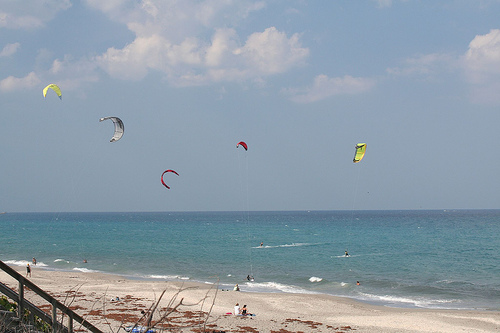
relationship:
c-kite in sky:
[159, 168, 180, 190] [1, 0, 480, 213]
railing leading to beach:
[6, 253, 109, 331] [4, 262, 498, 331]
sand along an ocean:
[4, 264, 498, 331] [4, 213, 498, 309]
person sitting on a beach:
[233, 302, 243, 316] [4, 262, 498, 331]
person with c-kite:
[224, 259, 264, 303] [235, 140, 249, 152]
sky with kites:
[0, 0, 500, 213] [177, 109, 283, 167]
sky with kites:
[0, 0, 500, 213] [48, 100, 385, 218]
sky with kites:
[35, 43, 495, 207] [97, 110, 426, 221]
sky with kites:
[0, 0, 500, 213] [45, 106, 226, 196]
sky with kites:
[0, 0, 500, 213] [115, 109, 387, 183]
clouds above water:
[122, 20, 333, 81] [88, 199, 496, 328]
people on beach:
[232, 300, 253, 318] [4, 233, 484, 331]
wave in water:
[300, 264, 337, 293] [0, 211, 484, 302]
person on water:
[244, 266, 262, 285] [5, 214, 480, 314]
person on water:
[344, 250, 350, 257] [5, 214, 480, 314]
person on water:
[354, 276, 371, 292] [5, 214, 480, 314]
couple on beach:
[230, 294, 254, 320] [4, 219, 466, 331]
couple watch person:
[230, 294, 254, 320] [356, 281, 359, 285]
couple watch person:
[230, 294, 254, 320] [246, 274, 251, 281]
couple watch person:
[230, 294, 254, 320] [344, 250, 350, 257]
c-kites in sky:
[35, 82, 370, 198] [1, 0, 480, 213]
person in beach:
[26, 263, 33, 277] [4, 219, 466, 331]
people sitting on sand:
[239, 304, 256, 316] [4, 264, 498, 331]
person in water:
[341, 240, 351, 263] [0, 211, 484, 302]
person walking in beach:
[22, 262, 34, 276] [5, 214, 495, 321]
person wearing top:
[232, 303, 239, 321] [232, 305, 243, 315]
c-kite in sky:
[42, 85, 63, 96] [1, 0, 480, 213]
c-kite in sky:
[104, 114, 123, 143] [1, 0, 480, 213]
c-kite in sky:
[228, 136, 256, 159] [1, 0, 480, 213]